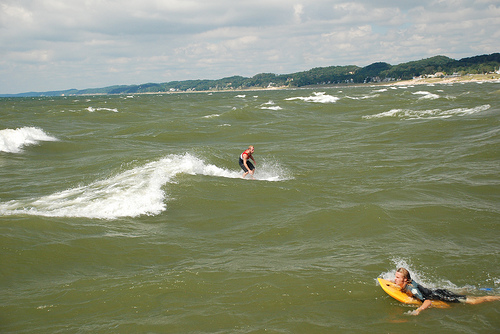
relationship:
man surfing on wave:
[240, 145, 257, 177] [97, 153, 304, 220]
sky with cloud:
[2, 1, 496, 82] [0, 0, 499, 75]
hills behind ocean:
[245, 55, 404, 110] [235, 95, 392, 167]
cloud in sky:
[0, 0, 499, 75] [2, 1, 496, 82]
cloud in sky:
[285, 15, 373, 46] [2, 1, 496, 82]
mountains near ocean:
[42, 45, 497, 89] [0, 79, 499, 333]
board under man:
[371, 274, 418, 307] [396, 272, 476, 308]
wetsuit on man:
[409, 271, 459, 303] [384, 213, 483, 328]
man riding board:
[393, 262, 479, 298] [365, 274, 462, 309]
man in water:
[393, 262, 479, 298] [399, 126, 468, 174]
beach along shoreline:
[231, 85, 498, 331] [86, 77, 498, 146]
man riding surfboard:
[389, 266, 500, 318] [368, 274, 425, 309]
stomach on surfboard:
[419, 292, 431, 302] [368, 274, 425, 309]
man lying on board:
[389, 266, 500, 318] [371, 275, 450, 310]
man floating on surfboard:
[389, 266, 500, 318] [380, 276, 450, 309]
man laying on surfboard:
[389, 266, 500, 318] [369, 262, 434, 316]